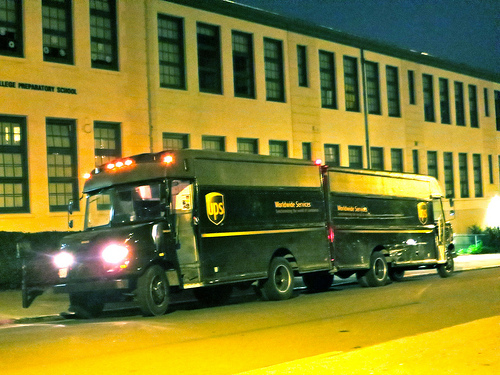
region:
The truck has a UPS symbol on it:
[186, 185, 234, 229]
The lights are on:
[49, 244, 137, 286]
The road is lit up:
[136, 317, 321, 363]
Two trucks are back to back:
[256, 118, 393, 315]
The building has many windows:
[58, 22, 498, 264]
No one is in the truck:
[82, 168, 190, 288]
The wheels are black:
[89, 256, 207, 342]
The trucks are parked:
[34, 248, 462, 303]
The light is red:
[301, 154, 328, 172]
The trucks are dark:
[167, 176, 319, 287]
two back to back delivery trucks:
[46, 148, 472, 315]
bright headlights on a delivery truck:
[47, 237, 146, 284]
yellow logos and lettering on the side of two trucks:
[190, 188, 433, 230]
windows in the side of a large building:
[148, 2, 293, 106]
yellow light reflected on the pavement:
[7, 298, 484, 365]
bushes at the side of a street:
[464, 220, 496, 252]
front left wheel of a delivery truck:
[132, 269, 174, 318]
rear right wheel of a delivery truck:
[351, 250, 389, 287]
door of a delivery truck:
[417, 193, 452, 268]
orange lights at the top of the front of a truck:
[76, 153, 182, 180]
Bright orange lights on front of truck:
[105, 151, 172, 168]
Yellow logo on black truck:
[204, 190, 228, 227]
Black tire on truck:
[141, 268, 172, 315]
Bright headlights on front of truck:
[57, 245, 134, 275]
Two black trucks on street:
[55, 148, 455, 315]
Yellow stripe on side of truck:
[200, 228, 325, 238]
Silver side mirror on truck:
[64, 200, 76, 228]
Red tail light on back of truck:
[327, 227, 335, 242]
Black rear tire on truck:
[359, 248, 391, 286]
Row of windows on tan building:
[155, 10, 287, 108]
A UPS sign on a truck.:
[205, 190, 227, 229]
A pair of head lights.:
[49, 240, 131, 271]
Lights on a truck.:
[79, 150, 177, 180]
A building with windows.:
[1, 0, 498, 240]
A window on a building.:
[156, 9, 191, 92]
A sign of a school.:
[0, 78, 78, 98]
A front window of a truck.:
[84, 185, 164, 230]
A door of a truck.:
[173, 179, 200, 286]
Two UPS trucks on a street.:
[54, 147, 462, 318]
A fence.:
[455, 229, 487, 255]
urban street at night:
[0, 266, 499, 373]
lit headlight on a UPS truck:
[100, 244, 127, 266]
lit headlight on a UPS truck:
[53, 252, 76, 270]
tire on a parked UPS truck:
[138, 266, 175, 315]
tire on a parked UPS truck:
[261, 256, 296, 300]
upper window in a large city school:
[152, 5, 192, 92]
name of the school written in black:
[0, 78, 77, 96]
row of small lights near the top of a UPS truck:
[83, 152, 180, 182]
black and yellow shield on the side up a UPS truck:
[203, 191, 228, 224]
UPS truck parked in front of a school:
[328, 166, 453, 286]